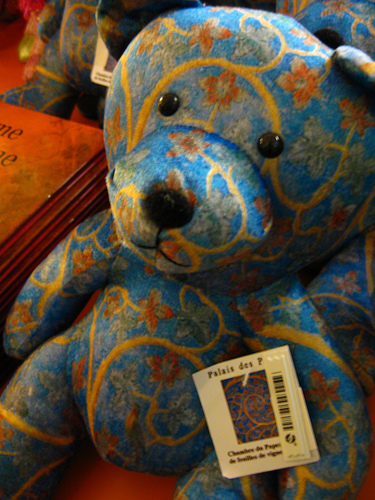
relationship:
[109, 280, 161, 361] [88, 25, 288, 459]
pattern on bear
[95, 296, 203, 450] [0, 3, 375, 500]
design on bear